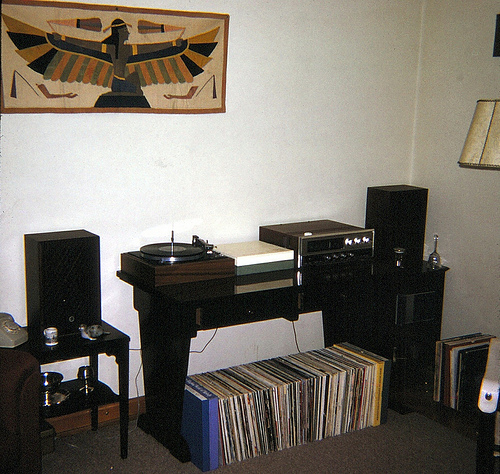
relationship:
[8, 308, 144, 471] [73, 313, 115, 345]
table with item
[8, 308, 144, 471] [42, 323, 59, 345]
table with white cup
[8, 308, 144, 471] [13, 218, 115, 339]
table with item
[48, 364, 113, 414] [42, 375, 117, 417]
items on bottom shelf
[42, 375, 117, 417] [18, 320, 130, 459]
bottom shelf of table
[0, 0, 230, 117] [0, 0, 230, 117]
frame with frame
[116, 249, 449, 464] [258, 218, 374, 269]
desk with stereo component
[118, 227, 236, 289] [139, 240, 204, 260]
turntable with record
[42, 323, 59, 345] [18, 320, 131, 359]
white cup sitting on table top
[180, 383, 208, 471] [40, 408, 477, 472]
album stacked on floor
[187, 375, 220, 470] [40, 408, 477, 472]
album stacked on floor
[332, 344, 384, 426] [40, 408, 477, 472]
album stacked on floor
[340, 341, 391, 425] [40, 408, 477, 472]
album stacked on floor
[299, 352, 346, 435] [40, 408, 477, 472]
album stacked on floor